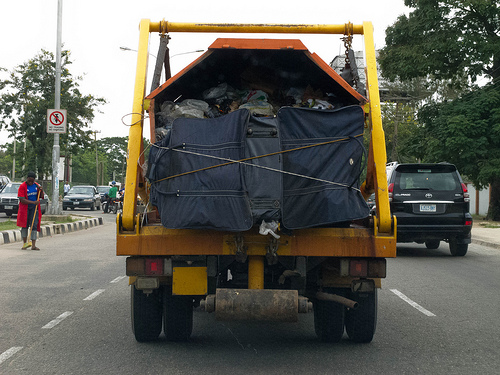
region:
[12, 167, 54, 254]
person walking down the street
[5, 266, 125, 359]
white dotted line painted on the road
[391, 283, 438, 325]
line that divides the lanes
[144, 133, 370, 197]
two ropes holding holding the cargo in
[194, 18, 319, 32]
rust on the yellow pole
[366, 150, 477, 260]
black car driving down the road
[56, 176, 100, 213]
car parked in a parking lot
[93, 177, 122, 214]
person on a bike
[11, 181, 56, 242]
long red jacket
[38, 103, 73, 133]
red, white, and black sign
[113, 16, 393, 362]
yellow operating garbage truck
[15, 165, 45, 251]
man standing with a stick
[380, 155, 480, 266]
SUV in the park position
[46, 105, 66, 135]
sign prohibiting a certain action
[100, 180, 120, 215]
motorcyclist stopped in traffic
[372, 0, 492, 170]
tree during the summer months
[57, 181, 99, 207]
car stuck in traffic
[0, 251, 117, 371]
road painted with white dotted lines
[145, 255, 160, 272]
inactive brake light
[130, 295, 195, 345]
double tires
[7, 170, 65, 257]
person with broom cleaning street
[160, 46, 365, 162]
garbage inside a garbage truck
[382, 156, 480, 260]
an SUV traveling down a road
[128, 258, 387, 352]
the back wheels of a garbage truck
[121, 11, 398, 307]
the back of a garbage truck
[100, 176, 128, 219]
a man on a bicycle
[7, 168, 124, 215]
cars parked in a parking lot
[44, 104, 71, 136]
a street sign along a road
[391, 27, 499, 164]
a tree next to a road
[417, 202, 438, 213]
the license plate of an SUV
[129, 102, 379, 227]
The rope holding the cargo in the truck.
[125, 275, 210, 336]
The two back wheels on the left of the yellow truck.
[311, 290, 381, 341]
The two back wheels on the right side of the yellow truck.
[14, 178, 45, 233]
The red coat the person sweeping is wearing.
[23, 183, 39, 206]
The blue t-shirt the person sweeping is wearing.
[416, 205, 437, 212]
The license plate on the black vehicle.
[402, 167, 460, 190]
The back window of the black vehicle.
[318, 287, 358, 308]
The muffler pipe on the back of the yellow truck.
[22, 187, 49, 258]
The broom in the person's hand that is sweeping.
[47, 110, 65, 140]
The street sign on the tall gray pole behind the person sweeping.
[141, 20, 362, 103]
this is a lorry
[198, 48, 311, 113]
the back is open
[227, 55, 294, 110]
the lorry has rubbish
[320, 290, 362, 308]
this is the exause pipe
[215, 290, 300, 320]
the metal is old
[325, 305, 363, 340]
these are two wheels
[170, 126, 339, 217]
the clothe is tied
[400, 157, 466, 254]
this is a car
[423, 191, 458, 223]
the car is black in color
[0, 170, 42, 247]
this is a woman